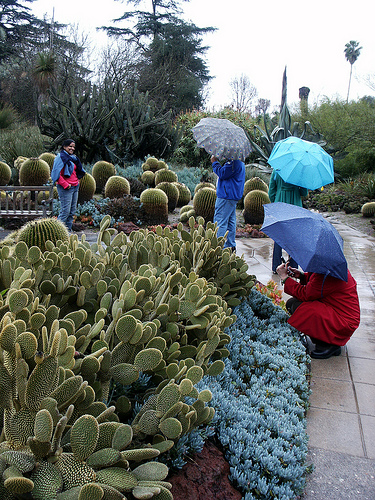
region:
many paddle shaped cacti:
[0, 280, 153, 497]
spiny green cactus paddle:
[68, 412, 98, 453]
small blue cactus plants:
[227, 425, 288, 482]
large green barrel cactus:
[16, 215, 65, 256]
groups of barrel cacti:
[91, 154, 176, 206]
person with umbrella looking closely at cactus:
[260, 198, 358, 355]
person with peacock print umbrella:
[188, 112, 251, 253]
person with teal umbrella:
[260, 132, 335, 208]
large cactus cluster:
[41, 78, 176, 157]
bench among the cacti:
[0, 184, 53, 223]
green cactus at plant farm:
[22, 413, 57, 447]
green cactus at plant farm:
[14, 157, 52, 193]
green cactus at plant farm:
[80, 166, 95, 196]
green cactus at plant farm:
[88, 155, 114, 175]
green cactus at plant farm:
[99, 167, 130, 193]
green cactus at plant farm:
[138, 188, 170, 217]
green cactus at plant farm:
[193, 190, 216, 215]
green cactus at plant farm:
[247, 190, 275, 215]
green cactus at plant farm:
[248, 169, 274, 189]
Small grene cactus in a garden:
[137, 170, 173, 233]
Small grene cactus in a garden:
[142, 390, 213, 435]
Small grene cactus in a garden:
[79, 425, 172, 498]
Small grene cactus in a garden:
[36, 412, 112, 495]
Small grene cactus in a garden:
[68, 341, 148, 416]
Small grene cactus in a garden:
[119, 300, 184, 381]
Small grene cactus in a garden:
[194, 182, 212, 223]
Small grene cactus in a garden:
[247, 188, 267, 211]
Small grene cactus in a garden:
[21, 148, 55, 191]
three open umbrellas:
[158, 75, 363, 306]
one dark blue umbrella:
[260, 189, 350, 277]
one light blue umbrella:
[266, 132, 334, 186]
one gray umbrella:
[194, 108, 261, 166]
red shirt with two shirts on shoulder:
[38, 144, 94, 221]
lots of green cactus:
[9, 220, 228, 496]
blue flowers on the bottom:
[228, 303, 301, 499]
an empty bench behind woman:
[1, 180, 70, 240]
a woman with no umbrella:
[31, 117, 121, 239]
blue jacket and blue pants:
[191, 153, 249, 259]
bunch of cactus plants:
[6, 233, 192, 483]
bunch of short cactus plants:
[6, 261, 197, 492]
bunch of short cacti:
[2, 260, 186, 493]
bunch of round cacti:
[5, 264, 189, 489]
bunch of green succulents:
[222, 307, 321, 498]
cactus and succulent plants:
[6, 270, 309, 491]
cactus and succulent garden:
[5, 294, 306, 494]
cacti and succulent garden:
[4, 293, 291, 491]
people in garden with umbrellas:
[194, 115, 365, 370]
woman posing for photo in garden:
[33, 127, 144, 271]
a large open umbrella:
[196, 105, 253, 163]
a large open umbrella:
[272, 133, 333, 188]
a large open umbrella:
[261, 196, 348, 274]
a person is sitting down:
[283, 243, 364, 358]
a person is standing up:
[209, 148, 250, 253]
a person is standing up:
[262, 164, 304, 271]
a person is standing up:
[54, 136, 81, 227]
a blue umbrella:
[256, 195, 352, 281]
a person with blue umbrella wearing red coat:
[254, 200, 366, 360]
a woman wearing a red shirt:
[45, 135, 84, 225]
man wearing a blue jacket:
[188, 110, 252, 246]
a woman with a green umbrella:
[264, 135, 341, 273]